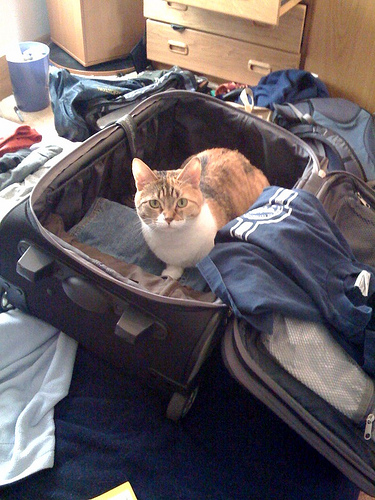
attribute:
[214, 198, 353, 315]
t shirt — blue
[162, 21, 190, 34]
clothes — article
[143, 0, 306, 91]
chest — light tan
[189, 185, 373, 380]
t-shirt — blue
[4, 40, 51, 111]
basket — small blue waste paper 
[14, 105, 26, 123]
pen — black marker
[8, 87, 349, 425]
suitcase — open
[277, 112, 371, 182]
strap — thick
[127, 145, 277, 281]
cat — brown, white, white and brown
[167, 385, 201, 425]
wheel — small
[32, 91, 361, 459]
suitcase — bottom